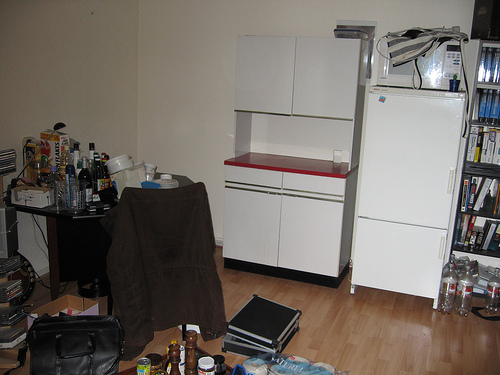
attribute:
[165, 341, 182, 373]
mill —  wood,  for salt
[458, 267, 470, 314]
water bottle —  for water,  empty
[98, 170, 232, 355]
jacket —  dark brown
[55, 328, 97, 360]
handle — black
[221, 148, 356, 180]
counter —  red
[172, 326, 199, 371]
pepper mill —  for  pepper,  wood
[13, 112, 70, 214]
desktop lamp —  small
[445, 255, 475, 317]
bottle —  empty,  for water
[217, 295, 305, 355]
case —  black,  metal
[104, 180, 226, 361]
jacket — brown